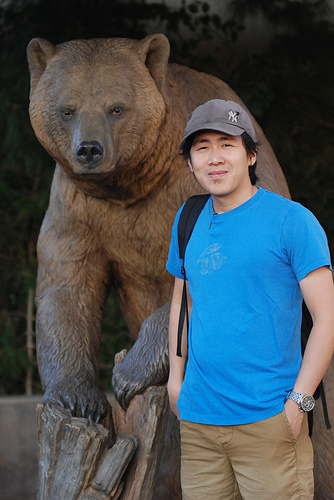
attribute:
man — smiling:
[166, 100, 333, 496]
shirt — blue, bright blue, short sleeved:
[165, 187, 333, 427]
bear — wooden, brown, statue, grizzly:
[26, 34, 294, 423]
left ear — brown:
[27, 37, 57, 88]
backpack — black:
[176, 193, 333, 438]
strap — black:
[174, 193, 210, 359]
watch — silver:
[288, 390, 317, 413]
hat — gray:
[176, 100, 258, 145]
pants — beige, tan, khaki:
[178, 409, 314, 498]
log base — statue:
[36, 349, 332, 500]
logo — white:
[228, 109, 240, 126]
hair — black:
[176, 129, 263, 187]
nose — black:
[73, 141, 106, 166]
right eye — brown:
[108, 103, 126, 117]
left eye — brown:
[60, 105, 73, 119]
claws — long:
[56, 396, 104, 423]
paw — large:
[42, 382, 113, 421]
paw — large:
[110, 359, 166, 411]